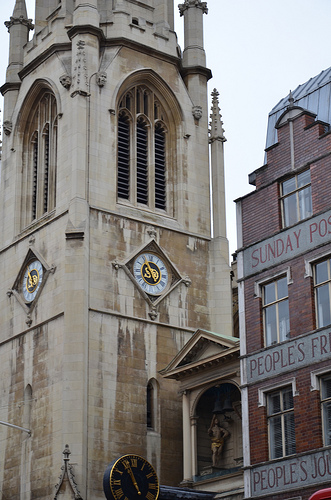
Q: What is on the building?
A: Clock.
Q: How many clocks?
A: 2.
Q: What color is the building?
A: White.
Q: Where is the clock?
A: On the building.